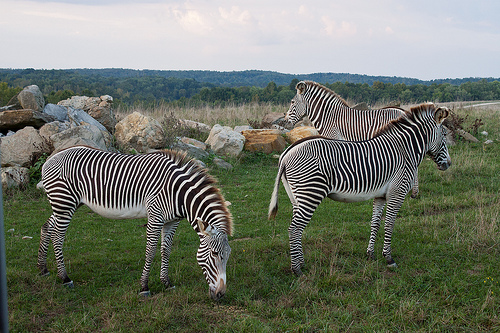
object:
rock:
[167, 136, 205, 155]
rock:
[201, 123, 246, 162]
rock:
[240, 127, 285, 155]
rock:
[16, 83, 46, 112]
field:
[0, 98, 499, 332]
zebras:
[282, 79, 422, 201]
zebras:
[264, 100, 453, 279]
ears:
[429, 105, 451, 126]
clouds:
[0, 0, 499, 83]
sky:
[0, 0, 499, 80]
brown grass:
[111, 96, 499, 125]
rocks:
[175, 117, 209, 135]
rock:
[42, 103, 69, 122]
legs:
[380, 187, 408, 265]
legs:
[47, 195, 75, 281]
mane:
[370, 102, 443, 138]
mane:
[302, 80, 350, 110]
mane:
[144, 148, 235, 238]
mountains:
[0, 68, 499, 110]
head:
[401, 102, 454, 172]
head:
[191, 217, 232, 300]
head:
[274, 78, 319, 130]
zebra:
[35, 144, 234, 301]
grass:
[0, 97, 499, 332]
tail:
[263, 161, 287, 226]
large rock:
[0, 122, 51, 168]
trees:
[0, 69, 499, 113]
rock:
[0, 162, 33, 194]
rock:
[112, 110, 166, 149]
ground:
[0, 100, 499, 333]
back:
[311, 130, 399, 158]